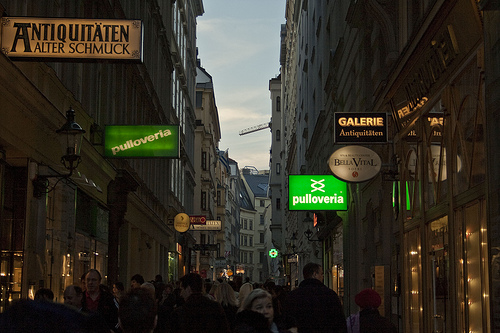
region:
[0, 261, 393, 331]
the people in front of the buildings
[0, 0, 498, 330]
the tall buildings lined up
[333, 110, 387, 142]
the lit up store sign that says GALERIE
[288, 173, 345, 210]
the lit up store sign that says pulloveria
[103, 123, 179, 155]
the lit up sign that says pulloveria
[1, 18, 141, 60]
the lit up sign that says ANTIQUITATEN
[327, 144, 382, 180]
the lit up sign that says BELLAVITAL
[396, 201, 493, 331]
the lit up window display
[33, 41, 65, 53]
the word ALTER on the lit up sign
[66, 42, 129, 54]
the word SCHMUCK on the lit up sign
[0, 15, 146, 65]
A sign that reads "Antiquitaten Alter Schmuck".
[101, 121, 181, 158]
A green sign reads "Pulloveria".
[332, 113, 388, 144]
A black sign with white letters reads "Galerie Antiquitaten".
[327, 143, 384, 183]
A white oval sign reads "Bella Vital".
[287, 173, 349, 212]
A green sign with white letters reads "Pulloveria".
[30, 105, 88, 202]
An ornate black light fixture.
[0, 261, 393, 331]
A crowd of people is on the street.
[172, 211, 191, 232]
A yellow oval sign.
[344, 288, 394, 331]
A woman wearing a red hat.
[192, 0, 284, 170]
The sunlight is fading.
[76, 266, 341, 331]
the street is parked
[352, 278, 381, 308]
the hat is red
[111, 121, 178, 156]
the sign is blue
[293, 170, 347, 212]
the sign is illuminated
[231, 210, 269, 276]
the building has windows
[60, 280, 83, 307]
the guy is bald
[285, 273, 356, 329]
the jacket is black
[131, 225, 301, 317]
the street is narrow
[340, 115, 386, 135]
the sign says galerie antiques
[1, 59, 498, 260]
the buildings are side to side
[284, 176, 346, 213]
green and white sign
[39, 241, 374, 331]
people walking down the street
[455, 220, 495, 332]
lights on the building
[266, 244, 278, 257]
green lights shining in the distance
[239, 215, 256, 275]
windows on the building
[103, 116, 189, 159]
sign hanging off the building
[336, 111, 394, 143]
black and white sign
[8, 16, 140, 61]
black writing on a white background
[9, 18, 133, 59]
black writing in all caps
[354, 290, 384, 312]
deep red hat on the head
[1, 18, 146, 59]
A store sign that reads 'ANTIQUITATEN'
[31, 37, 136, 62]
Black writing that reads 'ALTER SCHMUCK'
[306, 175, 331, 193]
A white brand logo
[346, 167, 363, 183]
A red brand logo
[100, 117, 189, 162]
A green sign that reads 'pulloveria'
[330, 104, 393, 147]
A black store sign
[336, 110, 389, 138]
The words 'GALERIE Antiquitaten'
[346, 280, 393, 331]
A person wearing a red cap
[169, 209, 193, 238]
A tan colored store sign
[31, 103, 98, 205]
A black street light